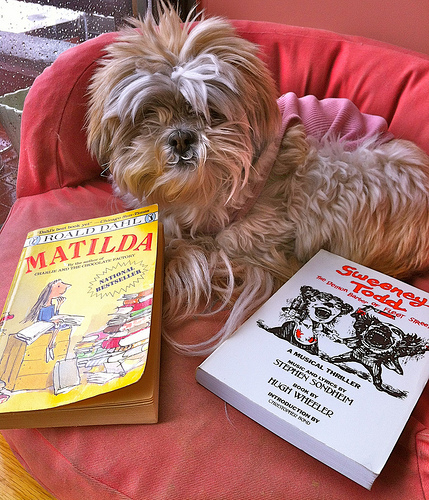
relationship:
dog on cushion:
[80, 6, 422, 273] [6, 184, 227, 347]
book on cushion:
[3, 205, 163, 442] [6, 184, 227, 347]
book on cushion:
[194, 246, 420, 492] [6, 184, 227, 347]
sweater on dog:
[176, 90, 397, 240] [54, 1, 415, 353]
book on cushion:
[3, 205, 163, 442] [2, 180, 426, 496]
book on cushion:
[194, 246, 420, 492] [2, 180, 426, 496]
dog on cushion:
[80, 0, 428, 357] [2, 180, 426, 496]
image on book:
[246, 284, 427, 402] [194, 246, 420, 492]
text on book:
[19, 232, 156, 271] [3, 205, 163, 442]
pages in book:
[0, 224, 166, 431] [18, 212, 179, 421]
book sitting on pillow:
[3, 205, 163, 442] [1, 169, 422, 496]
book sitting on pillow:
[194, 246, 420, 492] [1, 169, 422, 496]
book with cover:
[3, 205, 163, 442] [3, 200, 167, 431]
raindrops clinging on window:
[0, 0, 133, 229] [1, 0, 132, 232]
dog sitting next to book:
[80, 0, 428, 357] [194, 246, 420, 492]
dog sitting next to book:
[80, 0, 428, 357] [3, 205, 163, 442]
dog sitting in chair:
[80, 6, 422, 273] [7, 13, 419, 497]